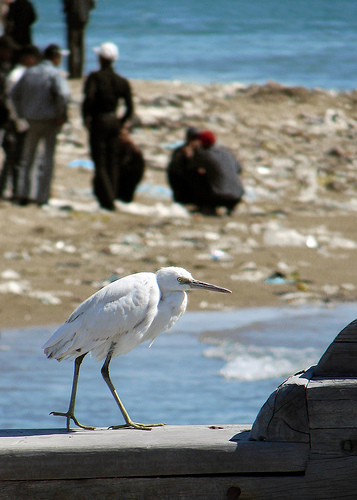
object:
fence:
[2, 322, 356, 500]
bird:
[43, 266, 231, 433]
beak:
[190, 278, 229, 295]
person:
[190, 132, 244, 213]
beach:
[1, 78, 355, 328]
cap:
[92, 42, 117, 59]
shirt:
[81, 68, 133, 127]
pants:
[88, 115, 121, 209]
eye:
[180, 278, 188, 286]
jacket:
[190, 148, 244, 199]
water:
[27, 2, 354, 95]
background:
[1, 2, 355, 314]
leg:
[102, 346, 132, 422]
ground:
[1, 76, 350, 332]